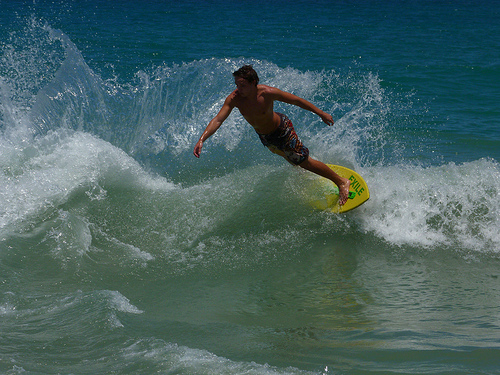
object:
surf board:
[302, 164, 369, 213]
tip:
[359, 186, 369, 204]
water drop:
[135, 66, 137, 68]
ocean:
[1, 0, 498, 372]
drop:
[113, 46, 116, 48]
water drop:
[153, 53, 155, 55]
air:
[0, 0, 499, 120]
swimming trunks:
[259, 111, 308, 166]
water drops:
[0, 3, 88, 91]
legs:
[336, 177, 350, 205]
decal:
[348, 175, 364, 196]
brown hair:
[232, 64, 259, 87]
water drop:
[125, 15, 128, 17]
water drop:
[315, 26, 316, 27]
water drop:
[471, 68, 473, 70]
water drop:
[407, 65, 409, 67]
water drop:
[454, 8, 456, 10]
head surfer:
[232, 64, 259, 97]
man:
[193, 65, 350, 205]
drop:
[360, 57, 362, 59]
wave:
[0, 28, 499, 272]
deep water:
[0, 66, 193, 236]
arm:
[273, 88, 317, 114]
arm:
[198, 96, 234, 141]